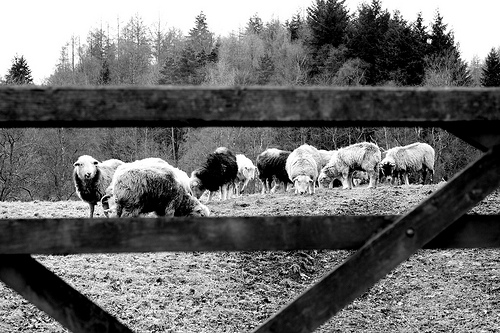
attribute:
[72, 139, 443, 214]
sheep — feeding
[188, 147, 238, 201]
sheep — dark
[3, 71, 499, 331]
fence — old, wooden, dark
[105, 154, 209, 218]
sheep — fluffy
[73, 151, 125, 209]
sheep — fluffy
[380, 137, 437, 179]
sheep — fluffy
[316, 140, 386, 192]
sheep — fluffy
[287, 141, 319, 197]
sheep — fluffy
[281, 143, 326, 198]
sheep — white, feeding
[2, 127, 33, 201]
leafless tree — small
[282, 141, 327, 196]
sheep — white, wooly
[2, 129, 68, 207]
branches — brown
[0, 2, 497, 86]
sky — gray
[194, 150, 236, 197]
sheep — dark